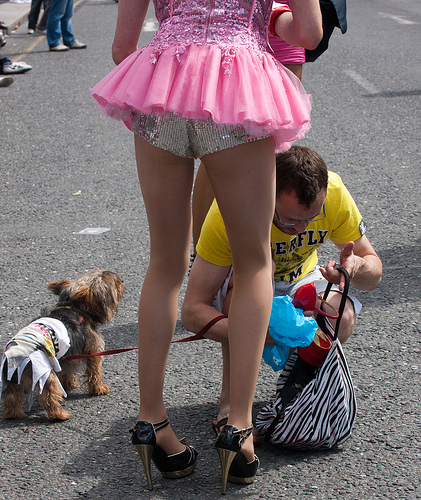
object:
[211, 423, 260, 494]
shoe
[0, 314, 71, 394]
shirt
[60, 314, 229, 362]
leash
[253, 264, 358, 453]
bag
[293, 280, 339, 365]
shoe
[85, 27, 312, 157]
tut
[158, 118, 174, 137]
sequins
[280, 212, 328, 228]
glasses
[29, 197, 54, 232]
asphalt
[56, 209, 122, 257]
asphalt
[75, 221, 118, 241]
trash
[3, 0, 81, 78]
lines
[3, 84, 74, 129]
asphalt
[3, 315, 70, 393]
dressed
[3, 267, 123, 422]
dog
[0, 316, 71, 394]
outfit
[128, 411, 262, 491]
two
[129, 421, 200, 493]
shoes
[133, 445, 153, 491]
heels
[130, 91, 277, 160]
short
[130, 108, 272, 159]
silver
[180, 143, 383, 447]
man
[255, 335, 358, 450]
zebra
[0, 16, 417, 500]
street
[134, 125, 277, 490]
two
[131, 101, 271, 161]
panties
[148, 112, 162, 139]
shiny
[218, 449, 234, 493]
gold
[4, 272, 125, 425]
little